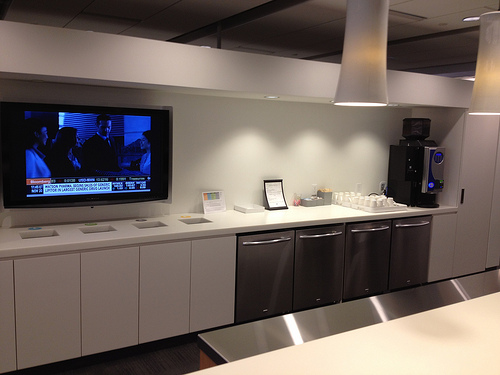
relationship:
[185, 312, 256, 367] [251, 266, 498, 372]
edge of tabletop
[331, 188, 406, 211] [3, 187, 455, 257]
cups on counter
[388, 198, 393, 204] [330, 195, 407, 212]
cups on a tray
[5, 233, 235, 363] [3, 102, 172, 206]
cabinets under tv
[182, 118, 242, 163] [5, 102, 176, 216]
wall near tv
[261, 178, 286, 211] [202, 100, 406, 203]
frame near wall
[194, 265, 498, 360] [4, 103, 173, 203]
steel counter across from television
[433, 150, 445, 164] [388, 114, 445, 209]
blue lights on a machine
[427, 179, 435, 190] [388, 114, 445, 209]
blue lights on a machine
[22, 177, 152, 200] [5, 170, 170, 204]
information on bottom